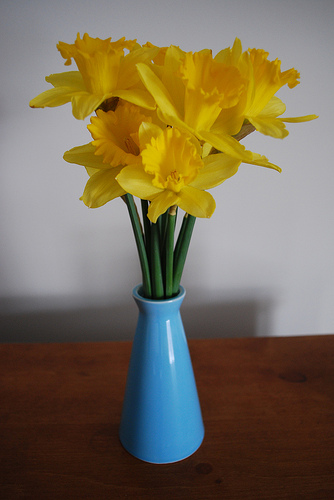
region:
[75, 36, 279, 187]
The flowers are yellow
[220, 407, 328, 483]
The table is wooden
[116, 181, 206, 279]
The stems are green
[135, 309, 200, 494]
The vase is blue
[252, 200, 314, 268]
The wall is white and clean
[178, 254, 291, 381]
There is a shadow on the wall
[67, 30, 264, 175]
The flowers are tulips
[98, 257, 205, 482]
The vase is narrow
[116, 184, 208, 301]
There are 4 stems in the front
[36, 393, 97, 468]
The table is wooden and brown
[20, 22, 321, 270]
a bunch of yellow daffodils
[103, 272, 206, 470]
a small blue modern vase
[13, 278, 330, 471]
a blue vase on a wooden table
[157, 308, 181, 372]
reflection of light on a blue vase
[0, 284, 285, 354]
shadow of the table on the wall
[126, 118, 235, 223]
yellow daffodil with petals open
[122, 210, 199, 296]
green daffodil stems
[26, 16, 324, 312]
daffodils in front of a white wall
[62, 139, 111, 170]
petal of a daffodil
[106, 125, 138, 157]
stamen of a daffodil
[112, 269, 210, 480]
blue vase on the table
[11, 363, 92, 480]
a wooden table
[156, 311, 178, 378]
a white reflection on the vase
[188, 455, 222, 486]
a dark spot on the wood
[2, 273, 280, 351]
a shadow on the wall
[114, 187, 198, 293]
green stems of the flowers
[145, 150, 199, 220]
middle of the flower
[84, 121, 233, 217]
yellow flower petals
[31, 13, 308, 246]
a bunch of yellow flowers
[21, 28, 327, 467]
yellow flowers in a blue vase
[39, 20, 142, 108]
Bright yellow flower petals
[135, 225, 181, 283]
Dark green flower stems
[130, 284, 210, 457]
Torquoise blue bud vase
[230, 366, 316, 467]
Wooden table top with knot in wood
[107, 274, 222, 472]
Cone shaped flower vase with green stems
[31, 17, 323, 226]
Yellow Spring flower bouquet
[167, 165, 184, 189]
Reproductive organs of the flower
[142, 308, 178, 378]
Reflection of lightsource and items on wall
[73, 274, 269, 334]
Shadow pattern on the back wall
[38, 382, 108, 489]
Woodgrain with stains and damage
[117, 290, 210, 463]
Small glass blue vase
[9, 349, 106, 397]
Large brown table top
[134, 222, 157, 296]
Dark green stem of flower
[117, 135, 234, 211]
Small bloomed yellow flower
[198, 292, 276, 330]
Dark grey shadow on wall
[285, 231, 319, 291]
Large smooth white wall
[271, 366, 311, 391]
Dark grain in wood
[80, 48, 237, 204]
Group of yellow flowers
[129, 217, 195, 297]
Group of green stems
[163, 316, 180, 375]
White reflection on vase